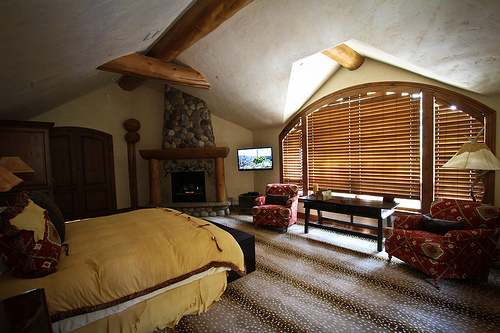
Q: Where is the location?
A: A bedroom.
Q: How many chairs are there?
A: Two.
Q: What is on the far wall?
A: Fireplace.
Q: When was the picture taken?
A: Day time.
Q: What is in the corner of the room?
A: Television.